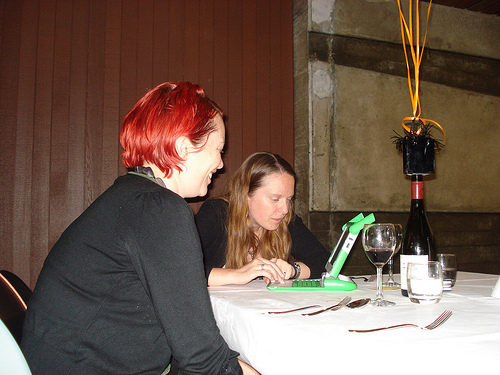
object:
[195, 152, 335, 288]
girl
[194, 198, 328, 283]
top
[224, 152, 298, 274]
hair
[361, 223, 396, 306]
glasses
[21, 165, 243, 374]
black shirt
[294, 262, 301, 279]
watch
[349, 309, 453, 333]
fork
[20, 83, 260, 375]
lady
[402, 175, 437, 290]
wine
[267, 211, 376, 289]
computer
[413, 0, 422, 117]
strings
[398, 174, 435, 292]
bottle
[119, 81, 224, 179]
red hair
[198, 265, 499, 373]
table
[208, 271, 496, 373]
cloth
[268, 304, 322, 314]
utensil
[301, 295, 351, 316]
utensil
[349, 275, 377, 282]
utensil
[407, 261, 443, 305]
cup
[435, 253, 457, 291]
cup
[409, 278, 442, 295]
water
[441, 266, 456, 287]
water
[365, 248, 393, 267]
wine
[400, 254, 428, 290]
label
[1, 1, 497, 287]
wall